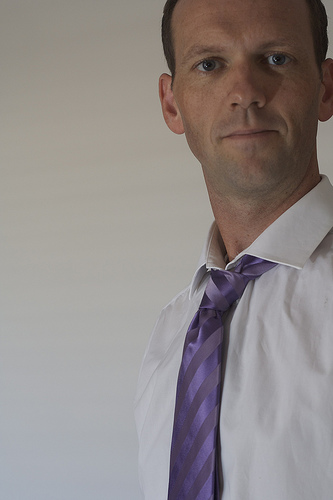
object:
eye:
[189, 43, 226, 83]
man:
[132, 1, 329, 500]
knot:
[203, 271, 236, 307]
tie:
[163, 262, 270, 500]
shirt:
[231, 280, 322, 470]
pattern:
[184, 349, 218, 426]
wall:
[23, 74, 166, 267]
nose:
[229, 52, 265, 108]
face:
[170, 0, 323, 201]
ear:
[152, 71, 182, 136]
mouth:
[216, 125, 284, 142]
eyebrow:
[256, 30, 299, 58]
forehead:
[167, 0, 320, 49]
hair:
[158, 21, 177, 47]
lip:
[222, 126, 277, 147]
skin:
[221, 199, 275, 243]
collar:
[262, 200, 314, 277]